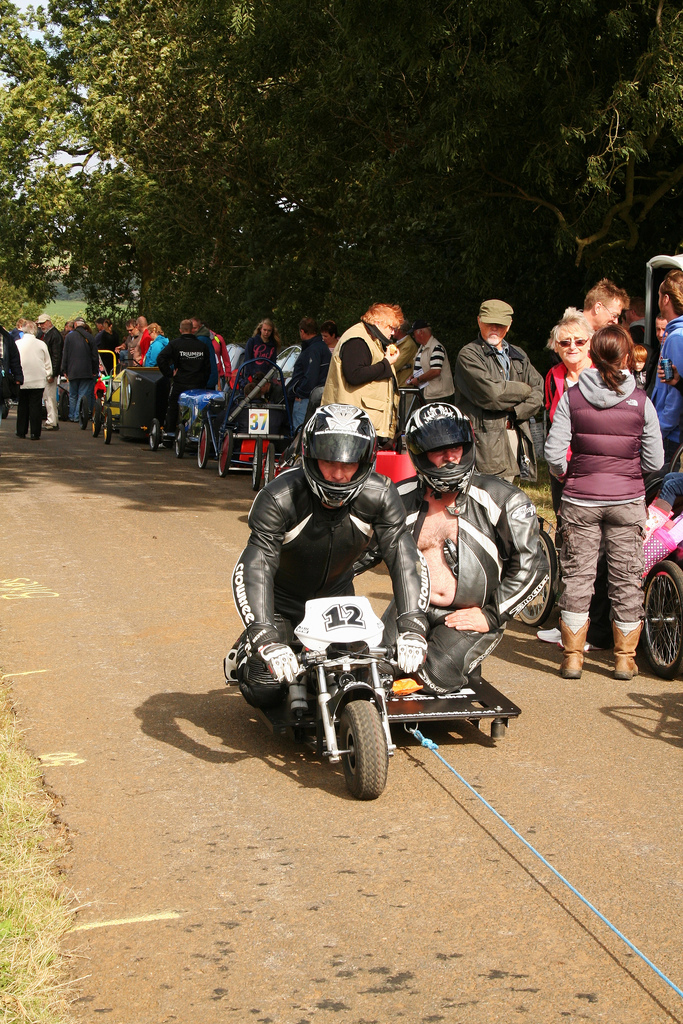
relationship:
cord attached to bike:
[417, 731, 671, 999] [222, 595, 517, 796]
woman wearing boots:
[542, 327, 667, 680] [556, 610, 591, 681]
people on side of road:
[1, 306, 100, 434] [7, 461, 658, 989]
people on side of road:
[102, 314, 277, 395] [7, 461, 658, 989]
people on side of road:
[282, 308, 445, 395] [7, 461, 658, 989]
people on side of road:
[479, 288, 680, 642] [7, 461, 658, 989]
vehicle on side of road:
[511, 512, 680, 641] [7, 461, 658, 989]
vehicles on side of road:
[152, 379, 285, 469] [7, 461, 658, 989]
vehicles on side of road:
[70, 339, 159, 449] [7, 461, 658, 989]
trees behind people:
[412, 6, 674, 324] [3, 311, 172, 426]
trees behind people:
[240, 6, 440, 332] [164, 303, 445, 434]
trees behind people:
[3, 6, 220, 314] [331, 276, 672, 664]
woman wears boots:
[558, 342, 650, 670] [561, 614, 650, 671]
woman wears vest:
[558, 342, 650, 670] [561, 388, 645, 506]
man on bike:
[239, 412, 412, 682] [222, 595, 517, 796]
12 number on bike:
[318, 599, 374, 638] [222, 595, 517, 796]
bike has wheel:
[222, 595, 517, 796] [288, 590, 483, 809]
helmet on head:
[298, 411, 376, 476] [298, 395, 376, 512]